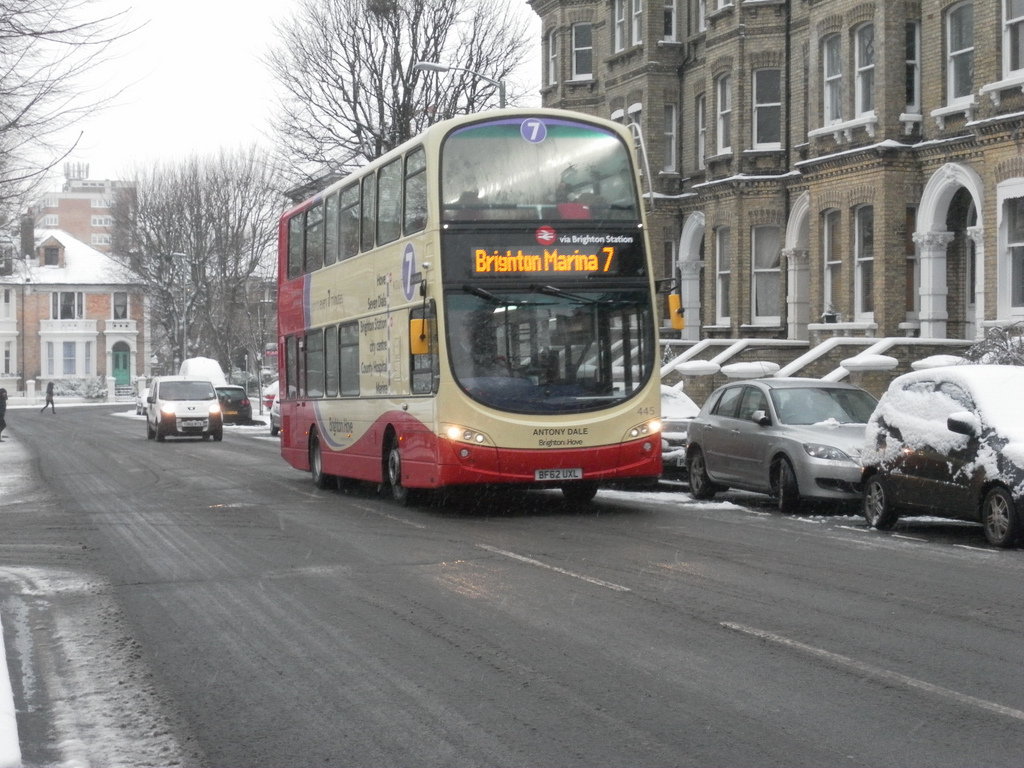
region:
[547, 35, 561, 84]
window in front of brownstone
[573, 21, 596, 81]
window in front of brownstone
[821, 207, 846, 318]
window in front of brownstone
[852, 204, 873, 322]
window in front of brownstone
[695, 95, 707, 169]
window in front of brownstone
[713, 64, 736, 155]
window in front of brownstone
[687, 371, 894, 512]
silver car parked on slushy street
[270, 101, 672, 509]
red and off-white double-decker bus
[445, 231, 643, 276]
sign on bus has gold letters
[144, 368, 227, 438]
white car with white headlights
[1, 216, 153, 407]
red brick and white roof building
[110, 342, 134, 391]
green door on front of house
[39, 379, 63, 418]
person crossing snowy street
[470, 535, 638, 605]
white line painted on road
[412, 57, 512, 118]
streetlight next to bus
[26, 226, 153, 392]
snow on roof of brick building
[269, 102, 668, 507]
red and tan double decker bus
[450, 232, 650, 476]
led sign with orange letters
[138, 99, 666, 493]
white van traveling behind bus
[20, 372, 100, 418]
person crossing street in front of building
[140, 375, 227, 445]
white van with headlights on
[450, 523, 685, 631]
white passing line on street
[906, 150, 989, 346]
white arch doorway on brick building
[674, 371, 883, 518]
a car parked on the side of the street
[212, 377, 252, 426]
a car parked on the side of the street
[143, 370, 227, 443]
a white van driving on the street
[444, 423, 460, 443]
the headlight of the bus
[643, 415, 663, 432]
the headlight of the bus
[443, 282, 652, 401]
the windshield of the bus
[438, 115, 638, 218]
the windshield of the bus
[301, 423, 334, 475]
the wheel of the bus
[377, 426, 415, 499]
the wheel of the bus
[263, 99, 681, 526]
Bus on a street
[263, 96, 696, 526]
Bus is on a street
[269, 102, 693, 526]
Bus on the road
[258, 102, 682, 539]
Double decker bus on the street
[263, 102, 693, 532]
Double decker bus is on the street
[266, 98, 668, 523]
Double decker bus on the road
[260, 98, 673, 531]
Double decker bus is on the road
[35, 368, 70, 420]
Person walking in the street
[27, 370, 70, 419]
Person walking on the road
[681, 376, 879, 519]
the parked snow covered car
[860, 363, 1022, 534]
the parked snow covered car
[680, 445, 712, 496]
the round rubber wheel of the car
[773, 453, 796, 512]
the round rubber wheel of the car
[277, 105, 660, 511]
large red blue and tan bus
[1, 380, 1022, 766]
A person crossing the street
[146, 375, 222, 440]
White car is being driven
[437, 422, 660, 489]
Headlights on top of the bumper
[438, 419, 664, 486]
A bumper under the headlights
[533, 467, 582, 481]
license plate with black numbers and letters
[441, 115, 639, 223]
number 7 on the window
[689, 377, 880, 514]
silver car is parked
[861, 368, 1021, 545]
black car is covered in snow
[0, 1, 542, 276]
sky is white and cloudy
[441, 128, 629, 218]
window of a bus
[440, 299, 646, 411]
window of a bus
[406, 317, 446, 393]
window of a bus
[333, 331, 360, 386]
window of a bus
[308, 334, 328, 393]
window of a bus